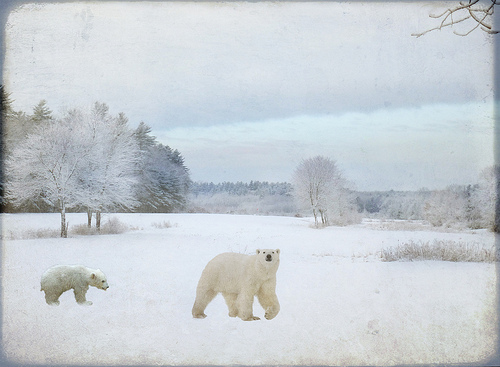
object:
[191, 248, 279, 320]
bear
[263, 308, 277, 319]
paw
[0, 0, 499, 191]
sky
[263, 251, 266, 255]
eye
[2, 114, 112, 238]
tree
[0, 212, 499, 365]
snow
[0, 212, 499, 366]
ground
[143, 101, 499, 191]
cloud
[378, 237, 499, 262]
grass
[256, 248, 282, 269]
head